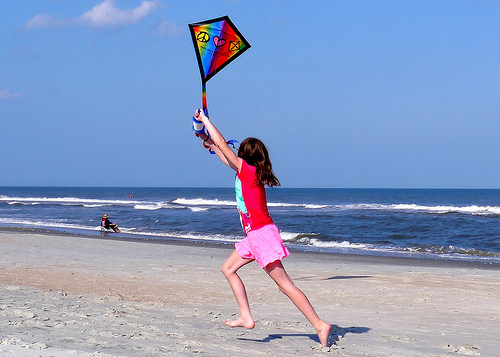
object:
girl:
[193, 108, 331, 350]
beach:
[1, 230, 499, 355]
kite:
[187, 16, 253, 115]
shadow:
[238, 320, 372, 348]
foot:
[223, 313, 256, 329]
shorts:
[233, 225, 292, 270]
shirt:
[234, 156, 275, 234]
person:
[101, 213, 121, 234]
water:
[1, 188, 499, 259]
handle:
[192, 109, 205, 135]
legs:
[257, 236, 332, 351]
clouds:
[21, 2, 190, 44]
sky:
[1, 1, 499, 187]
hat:
[103, 213, 111, 219]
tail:
[199, 82, 240, 157]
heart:
[211, 35, 226, 50]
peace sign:
[195, 30, 209, 44]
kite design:
[227, 38, 241, 52]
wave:
[3, 193, 499, 217]